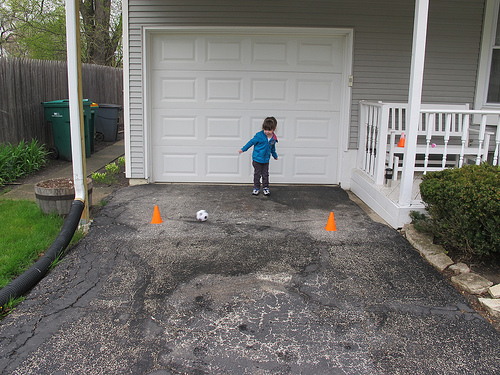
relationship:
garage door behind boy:
[145, 27, 348, 181] [235, 115, 280, 197]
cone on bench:
[395, 129, 407, 150] [377, 99, 494, 169]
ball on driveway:
[193, 204, 213, 227] [101, 171, 371, 368]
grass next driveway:
[2, 194, 66, 291] [2, 180, 497, 370]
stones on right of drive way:
[402, 223, 499, 316] [0, 183, 497, 373]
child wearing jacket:
[240, 114, 280, 195] [240, 129, 276, 166]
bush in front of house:
[409, 159, 499, 266] [61, 0, 498, 223]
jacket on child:
[239, 136, 282, 171] [240, 112, 284, 200]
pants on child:
[251, 161, 268, 192] [240, 114, 280, 195]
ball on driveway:
[195, 210, 208, 223] [2, 180, 497, 370]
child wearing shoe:
[240, 114, 280, 195] [251, 186, 258, 196]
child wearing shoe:
[240, 114, 280, 195] [261, 187, 269, 196]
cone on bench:
[302, 196, 354, 252] [374, 102, 480, 174]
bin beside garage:
[40, 98, 123, 162] [116, 24, 358, 169]